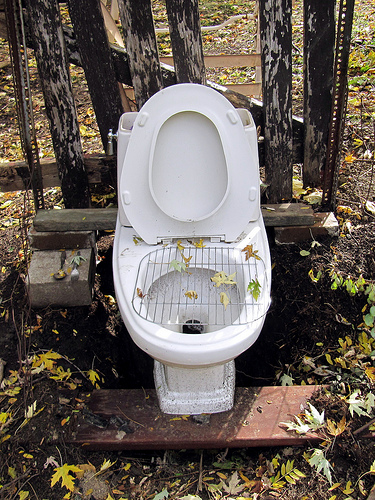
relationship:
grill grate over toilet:
[131, 245, 273, 326] [106, 82, 273, 417]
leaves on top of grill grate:
[136, 238, 261, 302] [131, 245, 273, 326]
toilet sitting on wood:
[106, 82, 273, 417] [68, 383, 333, 451]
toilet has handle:
[106, 82, 273, 417] [105, 125, 117, 157]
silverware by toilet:
[53, 249, 82, 282] [106, 82, 273, 417]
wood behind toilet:
[31, 201, 314, 231] [106, 82, 273, 417]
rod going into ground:
[317, 2, 355, 211] [2, 0, 373, 499]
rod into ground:
[3, 0, 46, 213] [2, 0, 373, 499]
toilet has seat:
[106, 82, 273, 417] [120, 83, 249, 243]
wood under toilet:
[68, 383, 333, 451] [106, 82, 273, 417]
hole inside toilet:
[182, 318, 203, 335] [106, 82, 273, 417]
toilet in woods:
[106, 82, 273, 417] [20, 1, 347, 208]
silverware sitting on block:
[53, 249, 82, 282] [24, 246, 97, 308]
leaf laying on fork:
[70, 256, 86, 265] [69, 249, 83, 283]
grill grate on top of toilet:
[131, 245, 273, 326] [106, 82, 273, 417]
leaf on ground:
[46, 447, 83, 494] [2, 0, 373, 499]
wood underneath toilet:
[68, 383, 333, 451] [106, 82, 273, 417]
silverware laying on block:
[53, 249, 82, 282] [24, 246, 97, 308]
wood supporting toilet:
[68, 383, 333, 451] [106, 82, 273, 417]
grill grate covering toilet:
[131, 245, 273, 326] [106, 82, 273, 417]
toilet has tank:
[106, 82, 273, 417] [118, 106, 262, 226]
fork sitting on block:
[69, 249, 83, 283] [24, 246, 97, 308]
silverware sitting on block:
[54, 251, 67, 279] [24, 246, 97, 308]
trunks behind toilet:
[24, 0, 336, 208] [106, 82, 273, 417]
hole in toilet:
[182, 318, 203, 335] [106, 82, 273, 417]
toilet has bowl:
[106, 82, 273, 417] [112, 227, 273, 368]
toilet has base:
[106, 82, 273, 417] [153, 359, 235, 417]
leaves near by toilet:
[2, 175, 371, 500] [106, 82, 273, 417]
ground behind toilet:
[2, 0, 373, 499] [106, 82, 273, 417]